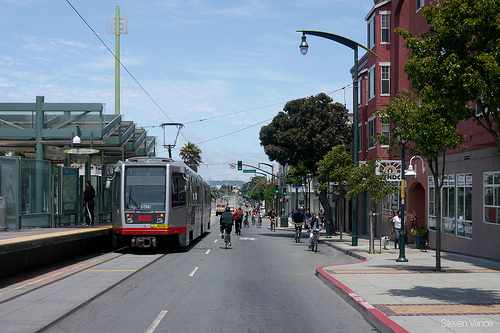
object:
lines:
[186, 261, 203, 278]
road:
[251, 263, 303, 304]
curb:
[326, 277, 355, 297]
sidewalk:
[400, 275, 459, 314]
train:
[108, 154, 187, 254]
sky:
[164, 14, 256, 40]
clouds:
[196, 80, 219, 115]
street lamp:
[292, 28, 371, 247]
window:
[376, 8, 397, 49]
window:
[373, 62, 396, 99]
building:
[343, 3, 416, 175]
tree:
[380, 29, 467, 269]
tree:
[402, 2, 498, 140]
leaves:
[390, 28, 441, 141]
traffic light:
[236, 158, 245, 172]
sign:
[373, 160, 403, 182]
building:
[331, 0, 500, 266]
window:
[365, 64, 374, 104]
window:
[352, 77, 363, 106]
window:
[377, 110, 393, 150]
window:
[365, 119, 378, 151]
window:
[481, 165, 500, 227]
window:
[427, 173, 438, 234]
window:
[451, 174, 473, 240]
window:
[440, 170, 454, 236]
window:
[362, 9, 378, 52]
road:
[1, 230, 373, 331]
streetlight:
[292, 28, 357, 61]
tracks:
[0, 249, 127, 332]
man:
[218, 206, 236, 245]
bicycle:
[219, 224, 234, 250]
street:
[2, 209, 377, 331]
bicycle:
[306, 229, 321, 252]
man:
[307, 212, 323, 247]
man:
[291, 207, 307, 238]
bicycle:
[290, 220, 304, 243]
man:
[266, 208, 277, 226]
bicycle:
[265, 214, 279, 231]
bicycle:
[234, 219, 244, 236]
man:
[234, 206, 245, 233]